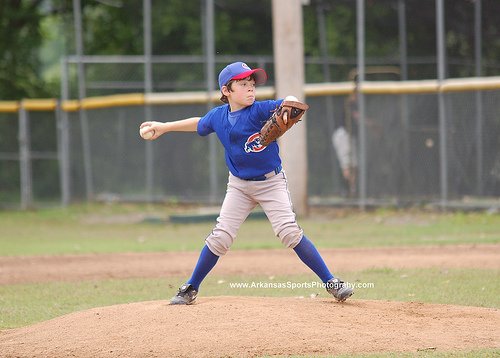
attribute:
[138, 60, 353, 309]
boy — pitching, throwing, playing baseball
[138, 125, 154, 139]
ball — being thrown, white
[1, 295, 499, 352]
pitcher's mound — dirt, here, light brown, brown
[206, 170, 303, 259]
pants — wrinkled, white, beige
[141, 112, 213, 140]
arm — extended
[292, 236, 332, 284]
sock — blue, long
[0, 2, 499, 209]
fence — chain link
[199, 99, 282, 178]
jersey — blue colored, blue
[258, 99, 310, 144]
baseball mitt — brown, seamed, leather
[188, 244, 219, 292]
sock — blue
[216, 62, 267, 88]
hat — red blue, black, blue, white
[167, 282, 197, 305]
shoe — black, cleated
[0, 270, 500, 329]
grass — green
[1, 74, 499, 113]
fence guard — yellow colored, yellow